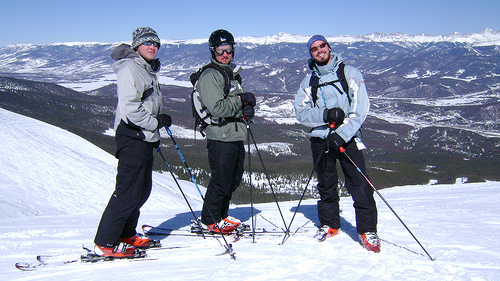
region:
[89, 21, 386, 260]
Three men standing at the top of a ski slope.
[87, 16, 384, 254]
Three skiers posing for a photo.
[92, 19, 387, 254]
Three men clothed to ski.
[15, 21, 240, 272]
Man in a grey jacket and black ski pants.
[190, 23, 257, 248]
Man with a backpack wearing a black helmet.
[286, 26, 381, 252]
Man in a light blue jacket and sunglasses.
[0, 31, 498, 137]
Snow covered mountains in the background.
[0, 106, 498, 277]
Snow covered area.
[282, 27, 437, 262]
Smiling man holding ski poles.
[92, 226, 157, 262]
Orange ski boots.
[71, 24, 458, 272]
three skiers on a mountain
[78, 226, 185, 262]
red ski boots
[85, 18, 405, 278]
skiers in black pants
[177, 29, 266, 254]
skier wearing a black helmet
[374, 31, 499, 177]
snowy mountain range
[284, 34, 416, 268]
skier wearing a blue beanie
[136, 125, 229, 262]
blue and black ski poles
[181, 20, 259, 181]
man with a backpack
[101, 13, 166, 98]
man wearing sunglasses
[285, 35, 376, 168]
man wearing a light blue jacket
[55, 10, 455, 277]
Three men posing for a picture.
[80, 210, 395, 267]
The men's ski boots are orange and white.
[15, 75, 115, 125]
The valley is covered in trees.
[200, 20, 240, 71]
A black helmet is on the man's head.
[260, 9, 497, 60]
A mountain range.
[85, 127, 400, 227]
Dark colored snow pants.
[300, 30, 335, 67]
The man is smiling.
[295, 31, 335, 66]
The man is wearing sunglasses.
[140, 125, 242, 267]
The man is holding ski poles.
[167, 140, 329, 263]
the snow is white and visible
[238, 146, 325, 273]
the snow is white and visible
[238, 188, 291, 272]
the snow is white and visible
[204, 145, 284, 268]
the snow is white and visible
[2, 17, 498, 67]
snowy background mountain tops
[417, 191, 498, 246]
flat snow on the ground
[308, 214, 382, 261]
red and white ski boots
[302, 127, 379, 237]
black ski pants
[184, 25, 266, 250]
man in center with green jacket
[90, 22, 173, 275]
man on left with knit beanie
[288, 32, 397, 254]
man on right with light blue coat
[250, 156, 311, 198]
trees in lower valley beyond skiers.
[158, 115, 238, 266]
blue ski poles held by left skier.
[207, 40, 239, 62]
black ski goggle eye protection